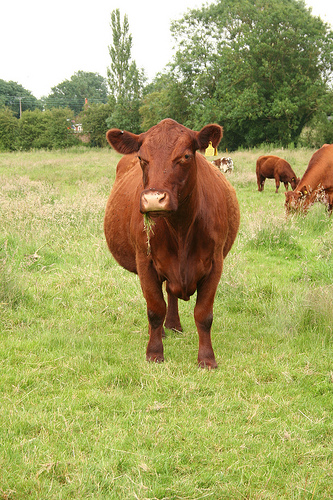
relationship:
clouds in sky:
[0, 0, 184, 60] [2, 0, 331, 85]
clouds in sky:
[7, 14, 89, 60] [0, 0, 174, 84]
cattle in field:
[103, 118, 240, 370] [2, 370, 331, 497]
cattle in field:
[103, 118, 240, 370] [3, 156, 329, 496]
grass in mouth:
[141, 212, 155, 254] [140, 206, 174, 215]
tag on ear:
[205, 141, 214, 158] [191, 123, 223, 153]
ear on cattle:
[191, 123, 223, 153] [103, 118, 240, 370]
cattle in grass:
[103, 118, 240, 370] [0, 141, 329, 497]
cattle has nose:
[103, 118, 240, 370] [141, 191, 176, 210]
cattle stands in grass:
[103, 118, 240, 370] [0, 141, 329, 497]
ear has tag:
[189, 123, 230, 155] [204, 145, 216, 160]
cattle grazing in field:
[102, 117, 240, 368] [0, 147, 333, 499]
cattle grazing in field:
[254, 155, 299, 193] [0, 147, 333, 499]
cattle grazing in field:
[282, 142, 330, 220] [0, 147, 333, 499]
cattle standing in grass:
[103, 118, 240, 370] [0, 141, 329, 497]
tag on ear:
[205, 141, 214, 157] [183, 108, 227, 157]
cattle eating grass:
[256, 155, 301, 194] [262, 214, 308, 271]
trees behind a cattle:
[3, 1, 332, 151] [103, 118, 240, 370]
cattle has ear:
[103, 118, 240, 370] [181, 113, 226, 165]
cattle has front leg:
[103, 118, 240, 370] [194, 253, 224, 374]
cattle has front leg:
[103, 118, 240, 370] [137, 266, 170, 362]